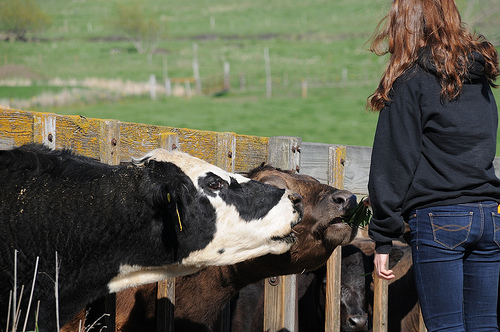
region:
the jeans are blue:
[432, 223, 495, 306]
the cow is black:
[52, 172, 277, 238]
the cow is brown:
[313, 172, 353, 238]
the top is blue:
[398, 104, 483, 176]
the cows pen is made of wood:
[97, 126, 242, 163]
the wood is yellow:
[68, 133, 154, 150]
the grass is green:
[242, 104, 339, 118]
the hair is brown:
[427, 57, 470, 83]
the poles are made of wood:
[231, 55, 293, 77]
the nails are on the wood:
[105, 140, 130, 148]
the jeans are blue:
[409, 198, 499, 330]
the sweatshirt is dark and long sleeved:
[366, 40, 496, 253]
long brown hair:
[366, 0, 494, 107]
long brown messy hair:
[367, 0, 493, 111]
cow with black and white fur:
[0, 140, 301, 328]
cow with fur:
[0, 141, 301, 327]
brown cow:
[175, 165, 360, 330]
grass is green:
[0, 0, 496, 162]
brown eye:
[207, 177, 218, 188]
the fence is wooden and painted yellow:
[0, 108, 389, 329]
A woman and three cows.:
[10, 8, 497, 313]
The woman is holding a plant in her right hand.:
[324, 2, 499, 329]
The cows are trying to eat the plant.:
[107, 101, 452, 319]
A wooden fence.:
[5, 96, 437, 330]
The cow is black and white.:
[16, 132, 306, 320]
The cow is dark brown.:
[173, 143, 365, 328]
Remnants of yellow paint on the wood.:
[12, 92, 257, 164]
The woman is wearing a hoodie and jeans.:
[376, 11, 498, 328]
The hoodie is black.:
[366, 46, 498, 211]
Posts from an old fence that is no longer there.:
[111, 37, 336, 112]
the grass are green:
[14, 5, 364, 136]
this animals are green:
[12, 145, 389, 312]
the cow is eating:
[315, 173, 382, 275]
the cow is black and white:
[8, 138, 306, 329]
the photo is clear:
[5, 1, 499, 323]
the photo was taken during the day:
[8, 7, 497, 327]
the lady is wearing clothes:
[365, 5, 499, 327]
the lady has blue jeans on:
[408, 207, 498, 330]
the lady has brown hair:
[348, 5, 499, 117]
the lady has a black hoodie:
[353, 39, 497, 225]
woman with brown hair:
[392, 12, 497, 330]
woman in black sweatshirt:
[386, 1, 480, 283]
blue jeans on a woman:
[399, 148, 488, 324]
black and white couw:
[8, 132, 298, 319]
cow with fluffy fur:
[10, 134, 310, 330]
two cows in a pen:
[5, 139, 318, 330]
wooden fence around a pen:
[19, 94, 346, 330]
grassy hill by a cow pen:
[51, 13, 442, 179]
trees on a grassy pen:
[15, 12, 310, 104]